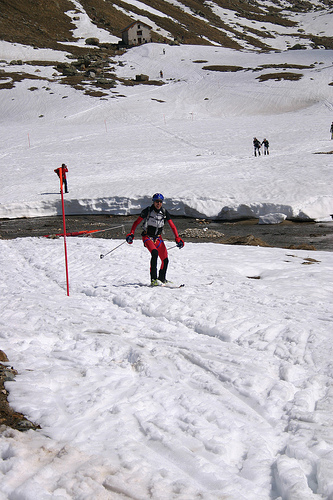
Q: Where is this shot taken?
A: Mountains.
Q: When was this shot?
A: Daytime.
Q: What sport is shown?
A: Skiing.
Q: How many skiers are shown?
A: 3.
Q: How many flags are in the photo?
A: 1.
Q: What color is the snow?
A: White.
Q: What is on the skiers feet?
A: Skis.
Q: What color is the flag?
A: Red.